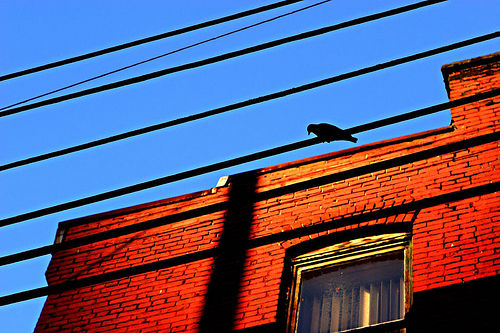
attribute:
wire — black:
[1, 85, 499, 228]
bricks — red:
[51, 263, 270, 333]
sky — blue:
[1, 2, 497, 211]